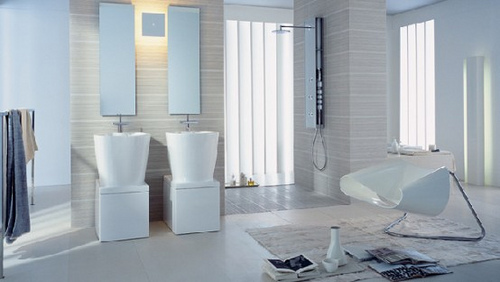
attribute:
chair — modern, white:
[289, 125, 449, 239]